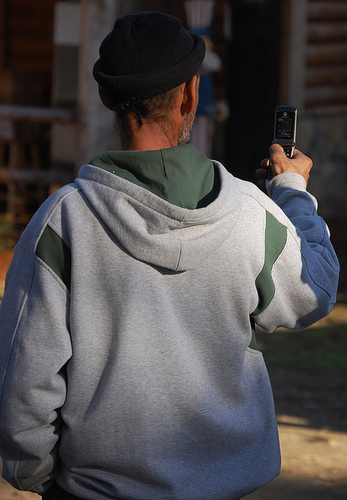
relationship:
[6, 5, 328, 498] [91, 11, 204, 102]
man wearing hat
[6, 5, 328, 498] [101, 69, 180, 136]
man has hair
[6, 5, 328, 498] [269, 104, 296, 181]
man looking at cellphone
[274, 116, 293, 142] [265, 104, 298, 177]
screen on cell phone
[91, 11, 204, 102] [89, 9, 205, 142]
hat on head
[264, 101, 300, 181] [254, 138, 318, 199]
cell phone in hand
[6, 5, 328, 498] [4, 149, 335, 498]
man wearing shirt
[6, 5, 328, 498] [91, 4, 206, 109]
man wearing hat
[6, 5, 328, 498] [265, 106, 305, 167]
man holding cellphone